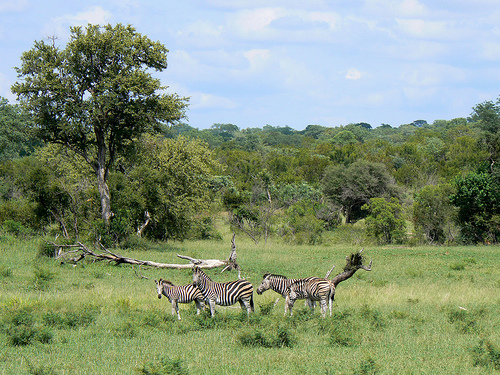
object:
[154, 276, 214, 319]
zebra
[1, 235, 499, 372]
field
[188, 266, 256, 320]
zebra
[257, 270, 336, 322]
zebra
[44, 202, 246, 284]
tree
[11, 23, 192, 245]
tree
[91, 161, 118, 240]
trunk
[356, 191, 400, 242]
foliage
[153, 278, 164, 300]
head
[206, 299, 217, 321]
leg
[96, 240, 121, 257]
branch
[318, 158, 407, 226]
tree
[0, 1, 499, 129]
sky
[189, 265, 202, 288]
head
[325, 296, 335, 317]
legs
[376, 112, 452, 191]
hills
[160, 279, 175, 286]
mane